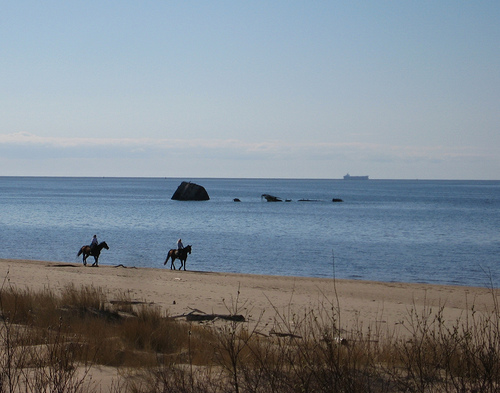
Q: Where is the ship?
A: On the horizon.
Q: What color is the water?
A: Blue.